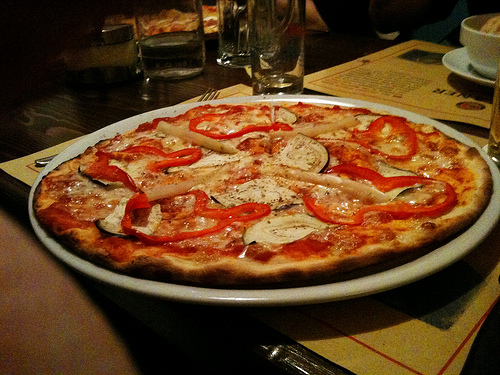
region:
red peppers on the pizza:
[228, 197, 268, 217]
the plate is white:
[236, 290, 270, 307]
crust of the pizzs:
[214, 262, 251, 283]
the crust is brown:
[254, 258, 300, 278]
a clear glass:
[242, 15, 302, 82]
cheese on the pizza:
[420, 153, 446, 174]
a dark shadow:
[128, 318, 180, 366]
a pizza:
[126, 113, 429, 268]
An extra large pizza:
[46, 63, 487, 307]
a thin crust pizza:
[42, 83, 484, 316]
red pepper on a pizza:
[291, 125, 467, 259]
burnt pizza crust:
[35, 155, 147, 283]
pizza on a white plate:
[25, 12, 480, 345]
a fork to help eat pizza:
[11, 60, 443, 302]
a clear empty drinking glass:
[231, 1, 406, 145]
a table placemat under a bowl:
[305, 18, 499, 145]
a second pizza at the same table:
[62, 8, 447, 228]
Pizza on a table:
[21, 66, 486, 318]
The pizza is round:
[27, 74, 489, 308]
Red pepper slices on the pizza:
[60, 108, 490, 241]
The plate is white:
[36, 80, 490, 316]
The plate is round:
[30, 83, 484, 314]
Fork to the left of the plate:
[25, 80, 226, 166]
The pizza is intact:
[39, 90, 493, 299]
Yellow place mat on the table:
[40, 77, 492, 372]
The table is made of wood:
[11, 13, 392, 154]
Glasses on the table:
[120, 5, 328, 99]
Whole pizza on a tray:
[44, 103, 487, 286]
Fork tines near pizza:
[197, 85, 219, 101]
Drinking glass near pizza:
[245, 3, 308, 89]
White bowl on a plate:
[461, 13, 498, 73]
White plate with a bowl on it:
[437, 48, 499, 91]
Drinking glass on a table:
[132, 5, 212, 82]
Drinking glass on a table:
[211, 3, 252, 68]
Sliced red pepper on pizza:
[122, 190, 264, 235]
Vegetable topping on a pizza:
[279, 130, 329, 175]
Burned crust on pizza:
[128, 255, 295, 285]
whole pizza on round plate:
[26, 91, 496, 311]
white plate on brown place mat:
[5, 75, 495, 370]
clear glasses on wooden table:
[132, 2, 309, 94]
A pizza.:
[28, 88, 494, 308]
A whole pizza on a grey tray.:
[31, 88, 498, 303]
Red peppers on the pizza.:
[111, 116, 458, 246]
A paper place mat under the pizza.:
[7, 74, 498, 373]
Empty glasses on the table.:
[136, 0, 316, 95]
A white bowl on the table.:
[448, 10, 498, 90]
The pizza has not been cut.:
[31, 95, 491, 282]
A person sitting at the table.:
[296, 1, 489, 43]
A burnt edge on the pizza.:
[36, 198, 432, 286]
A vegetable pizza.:
[46, 102, 498, 279]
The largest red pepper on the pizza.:
[304, 161, 456, 224]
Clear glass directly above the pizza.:
[247, 1, 304, 93]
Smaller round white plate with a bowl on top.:
[442, 45, 494, 85]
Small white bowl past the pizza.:
[460, 15, 499, 77]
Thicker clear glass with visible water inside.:
[133, 3, 207, 79]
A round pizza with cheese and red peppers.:
[31, 100, 491, 290]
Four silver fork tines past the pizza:
[197, 85, 218, 101]